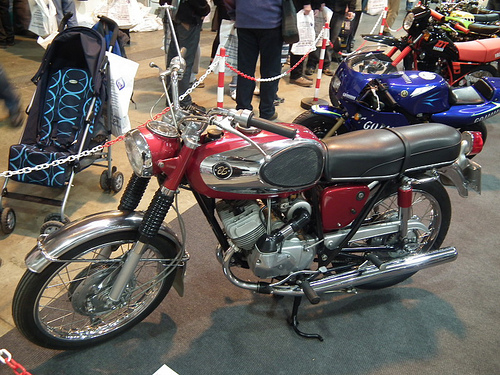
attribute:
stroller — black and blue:
[0, 32, 142, 242]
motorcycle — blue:
[291, 47, 488, 159]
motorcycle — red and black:
[311, 40, 498, 167]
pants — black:
[233, 24, 283, 121]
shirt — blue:
[230, 0, 282, 28]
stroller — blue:
[0, 18, 135, 243]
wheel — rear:
[330, 171, 452, 290]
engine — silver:
[209, 196, 460, 295]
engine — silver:
[328, 64, 499, 130]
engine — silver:
[402, 33, 499, 73]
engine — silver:
[439, 11, 499, 41]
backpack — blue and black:
[91, 15, 140, 129]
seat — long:
[265, 100, 466, 170]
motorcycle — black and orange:
[10, 38, 468, 372]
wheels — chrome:
[12, 211, 192, 348]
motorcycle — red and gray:
[99, 110, 497, 324]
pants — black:
[231, 22, 289, 124]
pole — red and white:
[212, 47, 226, 108]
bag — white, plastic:
[290, 8, 317, 55]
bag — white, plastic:
[206, 19, 238, 75]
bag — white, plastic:
[366, 1, 390, 14]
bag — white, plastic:
[314, 5, 333, 46]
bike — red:
[23, 47, 475, 342]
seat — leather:
[327, 119, 457, 171]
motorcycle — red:
[11, 41, 498, 352]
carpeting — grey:
[3, 203, 495, 373]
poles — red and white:
[128, 6, 361, 121]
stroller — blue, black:
[1, 10, 123, 235]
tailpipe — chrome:
[313, 245, 460, 288]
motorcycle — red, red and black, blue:
[0, 79, 478, 371]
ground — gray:
[171, 315, 274, 358]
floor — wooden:
[5, 39, 497, 374]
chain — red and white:
[221, 22, 324, 82]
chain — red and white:
[0, 47, 221, 178]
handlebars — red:
[142, 40, 302, 146]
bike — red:
[7, 5, 493, 355]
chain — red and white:
[4, 8, 385, 178]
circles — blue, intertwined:
[2, 67, 97, 187]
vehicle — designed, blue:
[292, 48, 498, 158]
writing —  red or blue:
[34, 71, 96, 161]